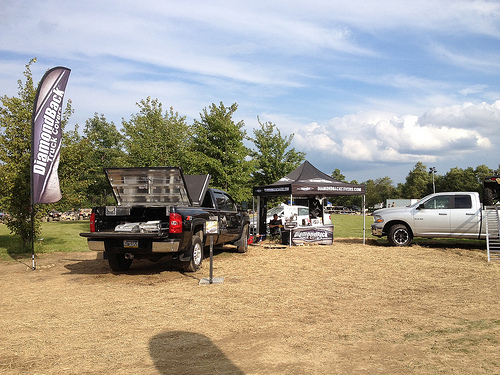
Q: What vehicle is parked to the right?
A: Pickup truck.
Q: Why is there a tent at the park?
A: To shield the sun.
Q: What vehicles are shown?
A: Trucks.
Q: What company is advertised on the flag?
A: Diamondback truck covers.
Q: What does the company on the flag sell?
A: Truck covers.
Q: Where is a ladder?
A: Leaning on silver truck.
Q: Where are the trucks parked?
A: Dirt.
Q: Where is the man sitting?
A: Under black awning.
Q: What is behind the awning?
A: Park with trees.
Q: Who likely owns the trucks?
A: Diamond back truck covers.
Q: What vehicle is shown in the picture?
A: Two trucks.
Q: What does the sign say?
A: Diamondback truck cover.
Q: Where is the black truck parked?
A: On a dirt area.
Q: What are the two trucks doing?
A: Parked.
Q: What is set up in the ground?
A: A tent.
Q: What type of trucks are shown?
A: A black and silver truck.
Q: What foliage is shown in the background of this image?
A: A group of green trees.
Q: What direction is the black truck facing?
A: Towards the tent.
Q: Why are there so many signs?
A: Advertising.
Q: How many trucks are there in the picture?
A: Two.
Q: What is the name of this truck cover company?
A: Diamondback.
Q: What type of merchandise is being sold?
A: Truck Covers.